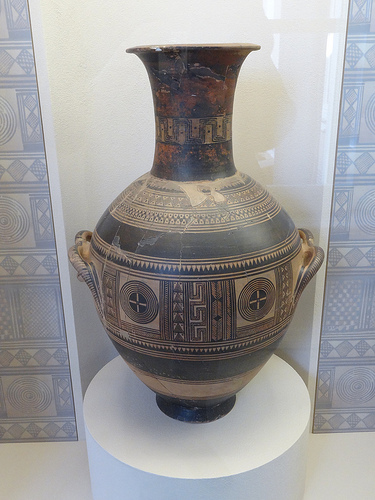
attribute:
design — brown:
[103, 249, 165, 344]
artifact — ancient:
[67, 33, 323, 435]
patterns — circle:
[111, 265, 160, 337]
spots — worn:
[180, 175, 225, 208]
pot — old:
[66, 37, 327, 426]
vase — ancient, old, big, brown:
[62, 39, 326, 432]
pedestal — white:
[77, 353, 314, 498]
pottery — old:
[62, 37, 329, 427]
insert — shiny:
[41, 1, 352, 402]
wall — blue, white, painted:
[0, 0, 362, 443]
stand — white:
[101, 368, 354, 487]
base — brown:
[147, 384, 265, 433]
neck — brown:
[125, 79, 251, 151]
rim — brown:
[111, 20, 280, 64]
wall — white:
[5, 58, 333, 475]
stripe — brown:
[86, 214, 310, 298]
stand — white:
[89, 345, 301, 492]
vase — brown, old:
[92, 30, 323, 439]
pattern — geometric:
[5, 78, 86, 434]